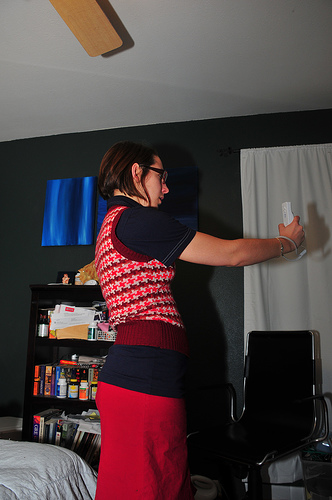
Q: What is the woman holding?
A: Game controller.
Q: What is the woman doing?
A: Playing video game.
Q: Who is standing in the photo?
A: A woman.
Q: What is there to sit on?
A: A black chair.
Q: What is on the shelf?
A: Books.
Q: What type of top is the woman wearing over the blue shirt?
A: A vest.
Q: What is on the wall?
A: A blue painting.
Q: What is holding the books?
A: A black shelf.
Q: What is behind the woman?
A: A bed.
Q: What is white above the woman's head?
A: The ceiling.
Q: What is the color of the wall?
A: Grey.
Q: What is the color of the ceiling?
A: White.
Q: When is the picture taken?
A: Night time.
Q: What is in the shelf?
A: Books.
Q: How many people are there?
A: 1.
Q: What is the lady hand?
A: Remote.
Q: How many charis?
A: One.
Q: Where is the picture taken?
A: In a bedroom.